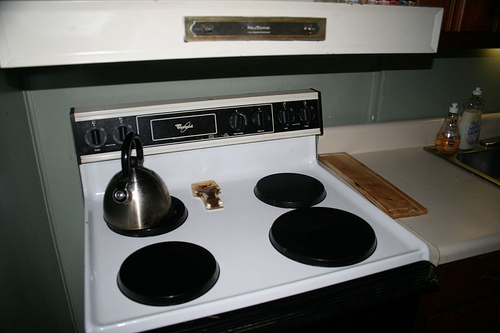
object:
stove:
[75, 98, 326, 292]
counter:
[359, 154, 464, 222]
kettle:
[104, 149, 163, 234]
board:
[329, 149, 422, 224]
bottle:
[441, 101, 460, 156]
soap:
[437, 129, 460, 150]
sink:
[466, 150, 500, 170]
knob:
[230, 111, 252, 137]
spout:
[117, 185, 130, 205]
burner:
[123, 241, 207, 296]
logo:
[166, 122, 196, 135]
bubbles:
[441, 134, 457, 151]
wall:
[132, 82, 231, 101]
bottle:
[471, 87, 480, 148]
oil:
[443, 133, 460, 153]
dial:
[88, 127, 107, 151]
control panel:
[77, 113, 324, 145]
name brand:
[170, 122, 206, 139]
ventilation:
[14, 1, 443, 74]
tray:
[423, 144, 459, 159]